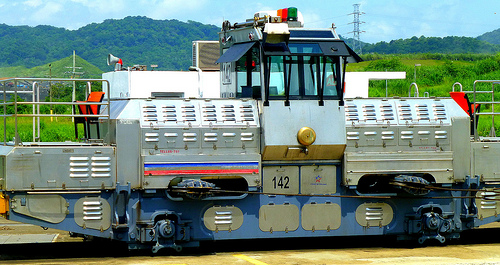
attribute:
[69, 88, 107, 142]
boat seat — orange, black, fold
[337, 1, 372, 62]
radio tower — electric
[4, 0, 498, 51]
background — blue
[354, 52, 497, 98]
mountain — grassy, green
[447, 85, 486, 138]
chair — orange, black, partially folded, red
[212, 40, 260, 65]
blue teal — blue metallic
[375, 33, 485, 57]
trees — green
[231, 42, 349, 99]
window — glass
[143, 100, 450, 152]
vents — white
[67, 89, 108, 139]
chair — fold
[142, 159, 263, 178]
stripe — blue, red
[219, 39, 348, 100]
area — small